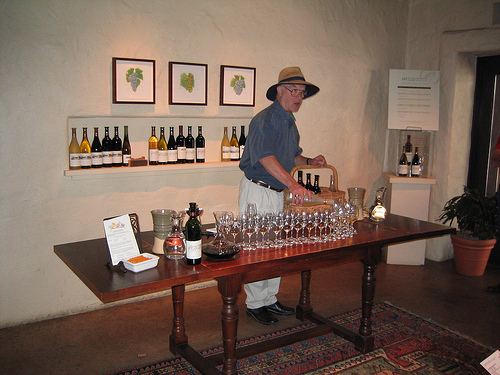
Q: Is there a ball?
A: No, there are no balls.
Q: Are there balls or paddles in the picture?
A: No, there are no balls or paddles.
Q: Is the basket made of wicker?
A: Yes, the basket is made of wicker.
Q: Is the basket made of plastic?
A: No, the basket is made of wicker.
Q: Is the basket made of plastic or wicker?
A: The basket is made of wicker.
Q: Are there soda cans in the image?
A: No, there are no soda cans.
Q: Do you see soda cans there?
A: No, there are no soda cans.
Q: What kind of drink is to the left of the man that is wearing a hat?
A: The drinks are wines.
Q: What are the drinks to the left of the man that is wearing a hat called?
A: The drinks are wines.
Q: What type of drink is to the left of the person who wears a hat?
A: The drinks are wines.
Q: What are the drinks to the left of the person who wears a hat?
A: The drinks are wines.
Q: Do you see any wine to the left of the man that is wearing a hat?
A: Yes, there are wines to the left of the man.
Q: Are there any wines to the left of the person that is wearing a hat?
A: Yes, there are wines to the left of the man.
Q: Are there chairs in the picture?
A: No, there are no chairs.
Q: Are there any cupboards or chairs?
A: No, there are no chairs or cupboards.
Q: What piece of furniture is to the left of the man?
A: The piece of furniture is a shelf.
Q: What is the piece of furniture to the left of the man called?
A: The piece of furniture is a shelf.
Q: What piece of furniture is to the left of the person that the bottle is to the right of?
A: The piece of furniture is a shelf.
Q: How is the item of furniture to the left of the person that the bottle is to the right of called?
A: The piece of furniture is a shelf.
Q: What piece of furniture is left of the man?
A: The piece of furniture is a shelf.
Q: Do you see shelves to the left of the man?
A: Yes, there is a shelf to the left of the man.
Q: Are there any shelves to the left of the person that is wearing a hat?
A: Yes, there is a shelf to the left of the man.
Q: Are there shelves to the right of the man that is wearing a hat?
A: No, the shelf is to the left of the man.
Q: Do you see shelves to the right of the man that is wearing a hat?
A: No, the shelf is to the left of the man.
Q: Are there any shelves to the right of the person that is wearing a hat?
A: No, the shelf is to the left of the man.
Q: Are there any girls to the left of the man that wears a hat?
A: No, there is a shelf to the left of the man.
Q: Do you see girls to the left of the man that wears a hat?
A: No, there is a shelf to the left of the man.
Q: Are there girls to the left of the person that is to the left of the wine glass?
A: No, there is a shelf to the left of the man.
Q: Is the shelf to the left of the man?
A: Yes, the shelf is to the left of the man.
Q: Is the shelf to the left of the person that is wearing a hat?
A: Yes, the shelf is to the left of the man.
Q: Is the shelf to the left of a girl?
A: No, the shelf is to the left of the man.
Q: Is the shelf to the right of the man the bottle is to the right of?
A: No, the shelf is to the left of the man.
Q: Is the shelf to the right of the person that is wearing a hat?
A: No, the shelf is to the left of the man.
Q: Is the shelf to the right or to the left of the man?
A: The shelf is to the left of the man.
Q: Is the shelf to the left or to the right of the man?
A: The shelf is to the left of the man.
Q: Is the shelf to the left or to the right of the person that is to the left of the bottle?
A: The shelf is to the left of the man.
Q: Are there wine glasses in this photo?
A: Yes, there is a wine glass.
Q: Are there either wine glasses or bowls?
A: Yes, there is a wine glass.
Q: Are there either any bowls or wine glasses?
A: Yes, there is a wine glass.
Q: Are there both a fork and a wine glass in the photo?
A: No, there is a wine glass but no forks.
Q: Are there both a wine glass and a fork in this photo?
A: No, there is a wine glass but no forks.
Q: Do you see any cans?
A: No, there are no cans.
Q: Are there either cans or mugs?
A: No, there are no cans or mugs.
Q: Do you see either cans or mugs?
A: No, there are no cans or mugs.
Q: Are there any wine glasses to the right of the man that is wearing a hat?
A: Yes, there is a wine glass to the right of the man.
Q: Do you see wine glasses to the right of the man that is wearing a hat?
A: Yes, there is a wine glass to the right of the man.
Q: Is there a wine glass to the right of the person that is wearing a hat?
A: Yes, there is a wine glass to the right of the man.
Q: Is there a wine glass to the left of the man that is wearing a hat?
A: No, the wine glass is to the right of the man.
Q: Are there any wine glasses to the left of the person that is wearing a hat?
A: No, the wine glass is to the right of the man.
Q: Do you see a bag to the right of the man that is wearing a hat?
A: No, there is a wine glass to the right of the man.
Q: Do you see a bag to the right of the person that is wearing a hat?
A: No, there is a wine glass to the right of the man.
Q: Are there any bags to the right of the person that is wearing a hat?
A: No, there is a wine glass to the right of the man.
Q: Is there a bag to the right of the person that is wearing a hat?
A: No, there is a wine glass to the right of the man.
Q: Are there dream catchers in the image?
A: No, there are no dream catchers.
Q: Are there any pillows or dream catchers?
A: No, there are no dream catchers or pillows.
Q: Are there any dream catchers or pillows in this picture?
A: No, there are no dream catchers or pillows.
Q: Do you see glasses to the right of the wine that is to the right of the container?
A: Yes, there are glasses to the right of the wine.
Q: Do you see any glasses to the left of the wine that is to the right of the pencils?
A: No, the glasses are to the right of the wine.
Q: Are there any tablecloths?
A: No, there are no tablecloths.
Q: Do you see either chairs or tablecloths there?
A: No, there are no tablecloths or chairs.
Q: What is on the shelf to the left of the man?
A: The wine bottles are on the shelf.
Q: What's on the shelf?
A: The wine bottles are on the shelf.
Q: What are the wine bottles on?
A: The wine bottles are on the shelf.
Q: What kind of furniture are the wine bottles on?
A: The wine bottles are on the shelf.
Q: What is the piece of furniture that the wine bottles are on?
A: The piece of furniture is a shelf.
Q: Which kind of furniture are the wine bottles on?
A: The wine bottles are on the shelf.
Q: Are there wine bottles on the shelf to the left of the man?
A: Yes, there are wine bottles on the shelf.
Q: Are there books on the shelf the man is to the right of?
A: No, there are wine bottles on the shelf.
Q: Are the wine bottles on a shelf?
A: Yes, the wine bottles are on a shelf.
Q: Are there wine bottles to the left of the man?
A: Yes, there are wine bottles to the left of the man.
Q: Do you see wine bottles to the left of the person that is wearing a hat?
A: Yes, there are wine bottles to the left of the man.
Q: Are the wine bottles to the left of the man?
A: Yes, the wine bottles are to the left of the man.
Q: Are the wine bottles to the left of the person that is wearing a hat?
A: Yes, the wine bottles are to the left of the man.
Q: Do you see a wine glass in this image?
A: Yes, there is a wine glass.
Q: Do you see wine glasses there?
A: Yes, there is a wine glass.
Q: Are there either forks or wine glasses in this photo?
A: Yes, there is a wine glass.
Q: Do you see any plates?
A: No, there are no plates.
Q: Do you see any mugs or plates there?
A: No, there are no plates or mugs.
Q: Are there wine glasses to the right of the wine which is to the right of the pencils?
A: Yes, there is a wine glass to the right of the wine.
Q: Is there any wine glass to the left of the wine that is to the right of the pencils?
A: No, the wine glass is to the right of the wine.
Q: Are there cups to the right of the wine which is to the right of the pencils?
A: No, there is a wine glass to the right of the wine.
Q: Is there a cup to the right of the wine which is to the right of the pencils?
A: No, there is a wine glass to the right of the wine.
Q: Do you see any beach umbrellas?
A: No, there are no beach umbrellas.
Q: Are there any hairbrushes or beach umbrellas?
A: No, there are no beach umbrellas or hairbrushes.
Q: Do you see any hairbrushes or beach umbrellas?
A: No, there are no beach umbrellas or hairbrushes.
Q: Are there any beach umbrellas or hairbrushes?
A: No, there are no beach umbrellas or hairbrushes.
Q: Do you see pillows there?
A: No, there are no pillows.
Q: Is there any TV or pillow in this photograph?
A: No, there are no pillows or televisions.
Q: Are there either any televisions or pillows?
A: No, there are no pillows or televisions.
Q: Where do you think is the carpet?
A: The carpet is on the floor.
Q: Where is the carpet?
A: The carpet is on the floor.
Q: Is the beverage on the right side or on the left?
A: The beverage is on the left of the image.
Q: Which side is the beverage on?
A: The beverage is on the left of the image.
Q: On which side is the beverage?
A: The beverage is on the left of the image.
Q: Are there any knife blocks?
A: No, there are no knife blocks.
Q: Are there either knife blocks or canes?
A: No, there are no knife blocks or canes.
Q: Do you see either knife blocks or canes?
A: No, there are no knife blocks or canes.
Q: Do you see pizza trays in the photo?
A: No, there are no pizza trays.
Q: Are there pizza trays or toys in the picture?
A: No, there are no pizza trays or toys.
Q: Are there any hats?
A: Yes, there is a hat.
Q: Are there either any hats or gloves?
A: Yes, there is a hat.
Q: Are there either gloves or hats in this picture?
A: Yes, there is a hat.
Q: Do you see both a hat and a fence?
A: No, there is a hat but no fences.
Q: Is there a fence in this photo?
A: No, there are no fences.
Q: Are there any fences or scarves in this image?
A: No, there are no fences or scarves.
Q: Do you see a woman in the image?
A: No, there are no women.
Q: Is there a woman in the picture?
A: No, there are no women.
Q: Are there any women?
A: No, there are no women.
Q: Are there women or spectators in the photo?
A: No, there are no women or spectators.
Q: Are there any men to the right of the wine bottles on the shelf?
A: Yes, there is a man to the right of the wine bottles.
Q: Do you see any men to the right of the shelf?
A: Yes, there is a man to the right of the shelf.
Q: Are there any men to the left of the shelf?
A: No, the man is to the right of the shelf.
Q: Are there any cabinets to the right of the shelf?
A: No, there is a man to the right of the shelf.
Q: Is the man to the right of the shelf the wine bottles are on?
A: Yes, the man is to the right of the shelf.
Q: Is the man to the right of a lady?
A: No, the man is to the right of the shelf.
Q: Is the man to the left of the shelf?
A: No, the man is to the right of the shelf.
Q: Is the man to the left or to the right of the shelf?
A: The man is to the right of the shelf.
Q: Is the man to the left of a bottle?
A: Yes, the man is to the left of a bottle.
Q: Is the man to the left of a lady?
A: No, the man is to the left of a bottle.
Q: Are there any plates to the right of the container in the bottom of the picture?
A: No, there is a man to the right of the container.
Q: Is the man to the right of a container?
A: Yes, the man is to the right of a container.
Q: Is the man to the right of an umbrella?
A: No, the man is to the right of a container.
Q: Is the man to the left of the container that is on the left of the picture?
A: No, the man is to the right of the container.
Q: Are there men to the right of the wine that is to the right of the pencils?
A: Yes, there is a man to the right of the wine.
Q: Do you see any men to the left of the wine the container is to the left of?
A: No, the man is to the right of the wine.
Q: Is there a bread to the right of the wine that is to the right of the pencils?
A: No, there is a man to the right of the wine.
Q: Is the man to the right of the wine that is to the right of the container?
A: Yes, the man is to the right of the wine.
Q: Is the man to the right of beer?
A: No, the man is to the right of the wine.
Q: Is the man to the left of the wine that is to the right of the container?
A: No, the man is to the right of the wine.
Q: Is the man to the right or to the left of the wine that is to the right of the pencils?
A: The man is to the right of the wine.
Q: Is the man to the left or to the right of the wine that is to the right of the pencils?
A: The man is to the right of the wine.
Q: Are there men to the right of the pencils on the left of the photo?
A: Yes, there is a man to the right of the pencils.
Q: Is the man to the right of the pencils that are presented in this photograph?
A: Yes, the man is to the right of the pencils.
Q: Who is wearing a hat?
A: The man is wearing a hat.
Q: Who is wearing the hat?
A: The man is wearing a hat.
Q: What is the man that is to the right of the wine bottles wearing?
A: The man is wearing a hat.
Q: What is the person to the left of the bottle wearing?
A: The man is wearing a hat.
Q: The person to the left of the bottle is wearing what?
A: The man is wearing a hat.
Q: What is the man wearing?
A: The man is wearing a hat.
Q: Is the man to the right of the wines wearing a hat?
A: Yes, the man is wearing a hat.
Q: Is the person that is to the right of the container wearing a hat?
A: Yes, the man is wearing a hat.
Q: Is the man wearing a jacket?
A: No, the man is wearing a hat.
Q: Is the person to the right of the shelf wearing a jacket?
A: No, the man is wearing a hat.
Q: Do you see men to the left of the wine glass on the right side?
A: Yes, there is a man to the left of the wine glass.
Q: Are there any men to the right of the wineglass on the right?
A: No, the man is to the left of the wine glass.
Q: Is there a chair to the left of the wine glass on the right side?
A: No, there is a man to the left of the wine glass.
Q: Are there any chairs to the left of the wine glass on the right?
A: No, there is a man to the left of the wine glass.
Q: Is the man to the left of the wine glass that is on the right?
A: Yes, the man is to the left of the wineglass.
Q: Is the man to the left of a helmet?
A: No, the man is to the left of the wineglass.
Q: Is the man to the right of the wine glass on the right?
A: No, the man is to the left of the wine glass.